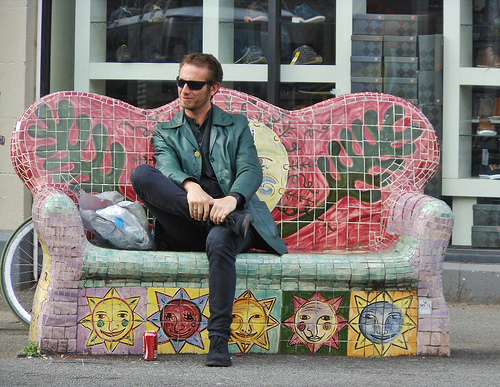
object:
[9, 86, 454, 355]
bench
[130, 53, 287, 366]
man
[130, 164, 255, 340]
jeans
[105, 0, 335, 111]
window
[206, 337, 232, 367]
shoe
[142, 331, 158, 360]
can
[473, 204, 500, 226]
stock box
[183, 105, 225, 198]
shirt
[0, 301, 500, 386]
ground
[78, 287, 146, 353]
sun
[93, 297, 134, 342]
face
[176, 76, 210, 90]
sunglasses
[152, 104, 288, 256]
jacket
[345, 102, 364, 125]
tile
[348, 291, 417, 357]
sun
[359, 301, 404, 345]
face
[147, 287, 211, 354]
sun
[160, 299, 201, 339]
face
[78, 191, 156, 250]
bag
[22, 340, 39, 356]
weed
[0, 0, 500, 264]
building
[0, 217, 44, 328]
bicycle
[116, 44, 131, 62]
shoe